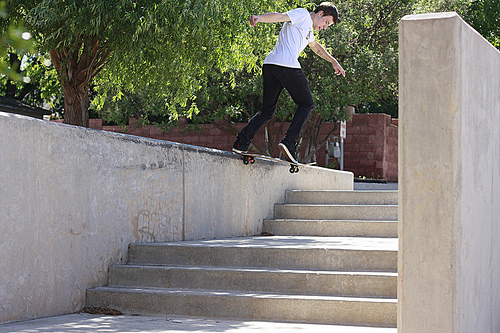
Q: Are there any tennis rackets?
A: No, there are no tennis rackets.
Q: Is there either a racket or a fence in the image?
A: No, there are no rackets or fences.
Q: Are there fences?
A: No, there are no fences.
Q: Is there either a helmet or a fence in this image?
A: No, there are no fences or helmets.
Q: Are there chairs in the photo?
A: No, there are no chairs.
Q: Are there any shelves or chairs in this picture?
A: No, there are no chairs or shelves.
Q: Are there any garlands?
A: No, there are no garlands.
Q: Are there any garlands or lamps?
A: No, there are no garlands or lamps.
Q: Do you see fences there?
A: No, there are no fences.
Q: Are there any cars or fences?
A: No, there are no fences or cars.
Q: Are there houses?
A: No, there are no houses.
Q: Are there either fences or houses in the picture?
A: No, there are no houses or fences.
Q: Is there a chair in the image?
A: No, there are no chairs.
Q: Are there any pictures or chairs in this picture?
A: No, there are no chairs or pictures.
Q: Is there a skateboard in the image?
A: Yes, there is a skateboard.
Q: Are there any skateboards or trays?
A: Yes, there is a skateboard.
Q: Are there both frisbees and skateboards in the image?
A: No, there is a skateboard but no frisbees.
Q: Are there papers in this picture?
A: No, there are no papers.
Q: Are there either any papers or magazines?
A: No, there are no papers or magazines.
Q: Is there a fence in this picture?
A: No, there are no fences.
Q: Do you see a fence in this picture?
A: No, there are no fences.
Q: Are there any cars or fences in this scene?
A: No, there are no fences or cars.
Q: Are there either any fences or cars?
A: No, there are no fences or cars.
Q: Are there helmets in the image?
A: No, there are no helmets.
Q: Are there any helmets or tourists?
A: No, there are no helmets or tourists.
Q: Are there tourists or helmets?
A: No, there are no helmets or tourists.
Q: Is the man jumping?
A: Yes, the man is jumping.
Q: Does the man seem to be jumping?
A: Yes, the man is jumping.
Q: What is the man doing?
A: The man is jumping.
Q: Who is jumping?
A: The man is jumping.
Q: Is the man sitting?
A: No, the man is jumping.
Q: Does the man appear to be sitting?
A: No, the man is jumping.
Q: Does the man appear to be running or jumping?
A: The man is jumping.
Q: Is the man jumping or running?
A: The man is jumping.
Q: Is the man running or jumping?
A: The man is jumping.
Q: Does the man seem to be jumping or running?
A: The man is jumping.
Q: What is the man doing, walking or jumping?
A: The man is jumping.